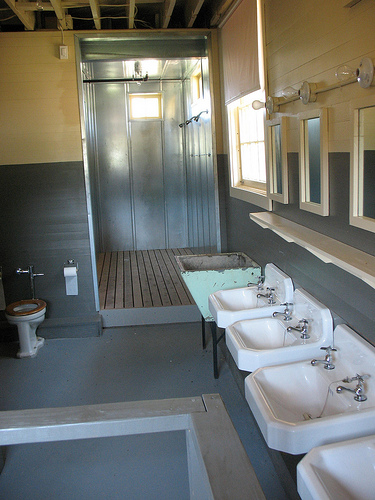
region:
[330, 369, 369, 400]
metal silver water faucet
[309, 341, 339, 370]
metal silver water faucet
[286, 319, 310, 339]
metal silver water faucet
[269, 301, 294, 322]
metal silver water faucet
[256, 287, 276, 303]
metal silver water faucet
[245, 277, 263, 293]
metal silver water faucet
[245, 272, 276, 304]
metal silver water faucets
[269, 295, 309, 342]
metal silver water faucets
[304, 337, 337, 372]
this is a tap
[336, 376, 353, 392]
the tap is metallic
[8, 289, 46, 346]
this is a toilet sink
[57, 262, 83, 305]
this is a tissue paper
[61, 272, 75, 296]
the tissue paper is white in color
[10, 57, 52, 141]
this is the wall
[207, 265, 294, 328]
a white sink on a wall.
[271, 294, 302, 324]
a metal sink faucet.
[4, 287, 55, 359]
a toilet in a bathroom.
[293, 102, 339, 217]
a mirror above a bathroom sink.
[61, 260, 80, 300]
a roll of toilet paper.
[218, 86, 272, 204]
a large bathroom window.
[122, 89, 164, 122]
a small window in a bathroom.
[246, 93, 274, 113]
a light in a bathroom.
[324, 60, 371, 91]
a light bulb in a bathroom.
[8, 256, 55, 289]
a metal flush handle.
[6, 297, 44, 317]
the toilet seat is down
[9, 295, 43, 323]
the toilet seat is down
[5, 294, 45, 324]
the toilet seat is down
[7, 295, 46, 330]
the toilet seat is down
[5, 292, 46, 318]
the toilet seat is down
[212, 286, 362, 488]
the sinks are clean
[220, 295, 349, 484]
the sinks are clean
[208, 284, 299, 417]
the sinks are clean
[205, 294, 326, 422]
the sinks are clean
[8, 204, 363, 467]
VIEW IS IN A BATHROOM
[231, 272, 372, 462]
4 sinks are arranged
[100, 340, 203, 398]
floor is gray in color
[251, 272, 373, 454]
sinks are fitted on the wall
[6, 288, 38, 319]
the toilet seat is made of wood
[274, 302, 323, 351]
the taps are silvery in color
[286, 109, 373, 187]
mirrors are fitted on the wall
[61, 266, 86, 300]
tissue roll is white in color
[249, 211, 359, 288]
shelf is white in color